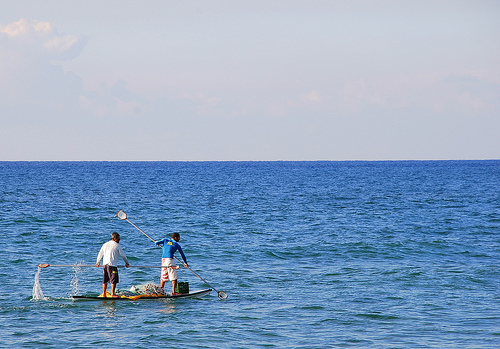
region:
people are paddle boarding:
[27, 211, 226, 303]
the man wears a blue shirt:
[155, 237, 190, 266]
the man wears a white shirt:
[95, 239, 127, 266]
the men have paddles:
[32, 207, 229, 299]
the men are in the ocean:
[0, 157, 499, 343]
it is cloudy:
[1, 0, 496, 161]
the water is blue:
[1, 161, 498, 345]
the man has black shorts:
[98, 264, 118, 284]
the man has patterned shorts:
[156, 255, 181, 280]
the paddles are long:
[43, 205, 228, 297]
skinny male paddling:
[96, 232, 128, 294]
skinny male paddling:
[156, 232, 193, 294]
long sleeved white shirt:
[96, 236, 126, 269]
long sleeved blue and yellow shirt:
[156, 238, 186, 263]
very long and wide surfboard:
[68, 284, 215, 301]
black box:
[172, 280, 188, 292]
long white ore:
[113, 207, 228, 299]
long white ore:
[38, 261, 180, 276]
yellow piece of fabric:
[97, 289, 139, 302]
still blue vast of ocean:
[1, 161, 497, 346]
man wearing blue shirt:
[147, 222, 187, 299]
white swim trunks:
[155, 251, 186, 289]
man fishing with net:
[144, 223, 200, 298]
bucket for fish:
[178, 279, 191, 294]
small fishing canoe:
[58, 278, 230, 304]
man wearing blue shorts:
[92, 230, 129, 302]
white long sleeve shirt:
[89, 237, 133, 276]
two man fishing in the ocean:
[89, 230, 219, 302]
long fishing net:
[22, 259, 159, 303]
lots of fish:
[126, 276, 173, 298]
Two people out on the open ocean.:
[40, 195, 267, 335]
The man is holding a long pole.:
[115, 205, 250, 305]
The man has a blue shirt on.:
[145, 215, 190, 305]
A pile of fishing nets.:
[112, 270, 167, 315]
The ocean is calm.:
[270, 180, 431, 320]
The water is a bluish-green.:
[296, 200, 448, 345]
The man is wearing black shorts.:
[80, 225, 130, 306]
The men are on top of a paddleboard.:
[30, 200, 225, 310]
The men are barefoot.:
[90, 215, 205, 305]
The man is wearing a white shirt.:
[85, 226, 127, 301]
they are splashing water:
[30, 255, 82, 299]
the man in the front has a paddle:
[116, 205, 230, 301]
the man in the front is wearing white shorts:
[158, 255, 182, 281]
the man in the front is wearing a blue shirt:
[153, 235, 190, 264]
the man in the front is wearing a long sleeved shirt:
[154, 236, 188, 265]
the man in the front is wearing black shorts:
[101, 262, 122, 286]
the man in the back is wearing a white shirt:
[98, 239, 125, 267]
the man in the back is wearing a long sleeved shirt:
[96, 237, 129, 268]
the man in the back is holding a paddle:
[38, 258, 182, 273]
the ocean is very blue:
[0, 159, 499, 347]